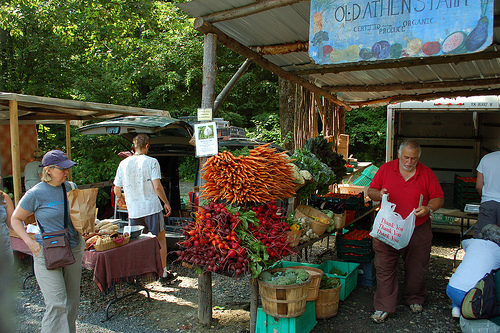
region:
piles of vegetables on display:
[172, 121, 349, 273]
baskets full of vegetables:
[254, 258, 349, 323]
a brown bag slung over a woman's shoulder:
[31, 183, 77, 275]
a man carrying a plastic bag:
[367, 135, 444, 320]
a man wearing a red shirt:
[368, 158, 444, 228]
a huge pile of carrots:
[197, 140, 302, 207]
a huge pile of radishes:
[177, 195, 295, 280]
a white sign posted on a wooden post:
[189, 116, 222, 163]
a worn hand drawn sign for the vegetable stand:
[304, 0, 499, 68]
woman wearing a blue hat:
[35, 142, 74, 174]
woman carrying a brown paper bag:
[9, 146, 99, 331]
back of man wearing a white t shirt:
[113, 134, 173, 224]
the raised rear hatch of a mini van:
[75, 110, 190, 140]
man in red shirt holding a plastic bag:
[366, 139, 443, 322]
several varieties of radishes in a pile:
[180, 199, 293, 279]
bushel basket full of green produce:
[255, 264, 313, 320]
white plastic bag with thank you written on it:
[369, 193, 417, 251]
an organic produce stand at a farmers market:
[179, 1, 496, 331]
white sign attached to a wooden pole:
[190, 17, 221, 157]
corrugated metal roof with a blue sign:
[173, 1, 498, 103]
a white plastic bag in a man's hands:
[370, 194, 419, 250]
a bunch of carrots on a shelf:
[199, 140, 298, 205]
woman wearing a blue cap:
[41, 148, 76, 170]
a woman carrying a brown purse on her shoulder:
[36, 185, 76, 269]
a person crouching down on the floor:
[446, 220, 498, 319]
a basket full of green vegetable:
[258, 263, 308, 317]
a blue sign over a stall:
[308, 1, 494, 63]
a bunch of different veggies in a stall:
[168, 137, 375, 275]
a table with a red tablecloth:
[12, 233, 157, 322]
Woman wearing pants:
[30, 232, 92, 332]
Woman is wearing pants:
[30, 235, 89, 330]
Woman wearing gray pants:
[29, 239, 89, 331]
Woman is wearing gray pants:
[31, 235, 84, 331]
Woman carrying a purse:
[28, 175, 78, 267]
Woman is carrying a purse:
[30, 175, 80, 272]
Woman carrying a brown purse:
[32, 177, 83, 274]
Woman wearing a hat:
[38, 147, 78, 174]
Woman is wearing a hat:
[37, 146, 82, 171]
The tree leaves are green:
[28, 8, 172, 81]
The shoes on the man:
[361, 300, 431, 327]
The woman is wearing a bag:
[20, 174, 81, 276]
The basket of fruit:
[249, 258, 323, 320]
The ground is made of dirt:
[136, 281, 203, 330]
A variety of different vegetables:
[175, 135, 357, 275]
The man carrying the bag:
[363, 175, 430, 253]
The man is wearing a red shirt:
[363, 149, 444, 233]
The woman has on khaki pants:
[28, 235, 92, 331]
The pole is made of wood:
[183, 32, 229, 332]